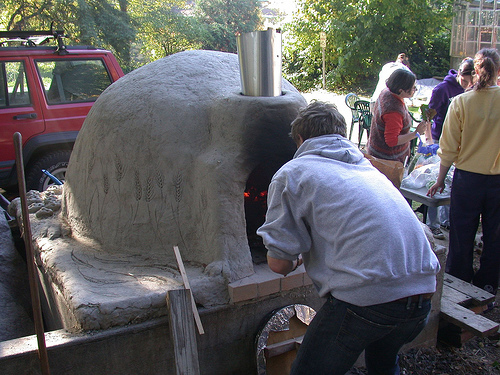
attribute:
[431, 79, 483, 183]
sweater — yellow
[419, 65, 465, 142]
top — purple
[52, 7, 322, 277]
oven — clay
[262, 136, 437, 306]
hoodie — grey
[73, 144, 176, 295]
designs — wheat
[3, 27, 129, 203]
vehicle — red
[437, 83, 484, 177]
sweater — yellow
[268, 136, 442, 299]
jacket — grey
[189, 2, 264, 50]
tree — tall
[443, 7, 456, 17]
leaves — green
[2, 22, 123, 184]
car — red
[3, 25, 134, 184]
car — red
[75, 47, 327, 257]
stone — grey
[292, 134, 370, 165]
hood — grey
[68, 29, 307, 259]
oven — clay, wood burning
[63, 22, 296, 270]
clay oven — large, grey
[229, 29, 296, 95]
exhaust pipe — silver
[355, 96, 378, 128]
green chair — plastic, outdoor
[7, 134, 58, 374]
wooden stick — long, brown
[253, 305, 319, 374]
shiny paper — silver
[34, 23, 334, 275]
outdoor stove — used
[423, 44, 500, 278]
woman's shirt — long sleeved, yellow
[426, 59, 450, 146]
girl's hoodie — purple